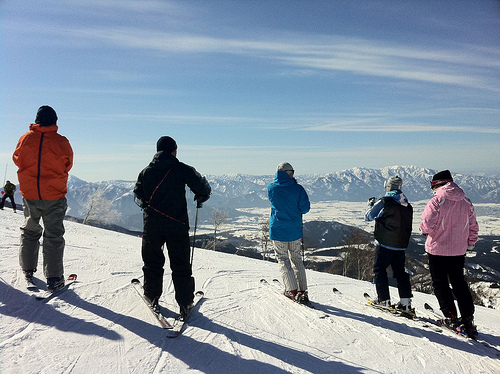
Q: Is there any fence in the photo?
A: No, there are no fences.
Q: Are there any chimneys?
A: No, there are no chimneys.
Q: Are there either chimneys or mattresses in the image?
A: No, there are no chimneys or mattresses.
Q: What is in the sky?
A: The clouds are in the sky.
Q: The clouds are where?
A: The clouds are in the sky.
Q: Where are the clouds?
A: The clouds are in the sky.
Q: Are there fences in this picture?
A: No, there are no fences.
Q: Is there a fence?
A: No, there are no fences.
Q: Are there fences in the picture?
A: No, there are no fences.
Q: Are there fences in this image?
A: No, there are no fences.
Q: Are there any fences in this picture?
A: No, there are no fences.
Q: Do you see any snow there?
A: Yes, there is snow.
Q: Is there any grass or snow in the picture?
A: Yes, there is snow.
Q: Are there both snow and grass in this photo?
A: No, there is snow but no grass.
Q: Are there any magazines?
A: No, there are no magazines.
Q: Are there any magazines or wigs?
A: No, there are no magazines or wigs.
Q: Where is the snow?
A: The snow is on the ground.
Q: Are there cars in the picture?
A: No, there are no cars.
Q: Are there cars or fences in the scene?
A: No, there are no cars or fences.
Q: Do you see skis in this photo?
A: Yes, there are skis.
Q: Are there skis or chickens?
A: Yes, there are skis.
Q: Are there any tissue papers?
A: No, there are no tissue papers.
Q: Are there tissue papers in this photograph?
A: No, there are no tissue papers.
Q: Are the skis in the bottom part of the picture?
A: Yes, the skis are in the bottom of the image.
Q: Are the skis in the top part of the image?
A: No, the skis are in the bottom of the image.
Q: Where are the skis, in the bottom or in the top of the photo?
A: The skis are in the bottom of the image.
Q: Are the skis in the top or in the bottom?
A: The skis are in the bottom of the image.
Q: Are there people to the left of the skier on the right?
A: Yes, there is a person to the left of the skier.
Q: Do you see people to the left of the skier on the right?
A: Yes, there is a person to the left of the skier.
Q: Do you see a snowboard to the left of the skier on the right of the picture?
A: No, there is a person to the left of the skier.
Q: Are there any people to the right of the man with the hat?
A: Yes, there is a person to the right of the man.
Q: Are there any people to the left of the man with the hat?
A: No, the person is to the right of the man.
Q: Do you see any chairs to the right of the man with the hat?
A: No, there is a person to the right of the man.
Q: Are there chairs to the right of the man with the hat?
A: No, there is a person to the right of the man.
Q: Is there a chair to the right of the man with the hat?
A: No, there is a person to the right of the man.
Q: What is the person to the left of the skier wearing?
A: The person is wearing a jacket.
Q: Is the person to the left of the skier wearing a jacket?
A: Yes, the person is wearing a jacket.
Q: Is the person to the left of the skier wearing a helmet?
A: No, the person is wearing a jacket.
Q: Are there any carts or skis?
A: Yes, there are skis.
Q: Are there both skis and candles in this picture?
A: No, there are skis but no candles.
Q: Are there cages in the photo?
A: No, there are no cages.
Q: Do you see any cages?
A: No, there are no cages.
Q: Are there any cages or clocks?
A: No, there are no cages or clocks.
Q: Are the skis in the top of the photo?
A: No, the skis are in the bottom of the image.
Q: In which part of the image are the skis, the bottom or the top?
A: The skis are in the bottom of the image.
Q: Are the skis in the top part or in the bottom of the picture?
A: The skis are in the bottom of the image.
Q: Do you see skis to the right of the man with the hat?
A: Yes, there are skis to the right of the man.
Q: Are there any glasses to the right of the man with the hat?
A: No, there are skis to the right of the man.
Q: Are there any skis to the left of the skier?
A: Yes, there are skis to the left of the skier.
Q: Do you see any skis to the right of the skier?
A: No, the skis are to the left of the skier.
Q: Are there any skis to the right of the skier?
A: No, the skis are to the left of the skier.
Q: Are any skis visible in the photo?
A: Yes, there are skis.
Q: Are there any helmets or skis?
A: Yes, there are skis.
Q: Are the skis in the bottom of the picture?
A: Yes, the skis are in the bottom of the image.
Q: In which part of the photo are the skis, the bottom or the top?
A: The skis are in the bottom of the image.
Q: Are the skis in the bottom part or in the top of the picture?
A: The skis are in the bottom of the image.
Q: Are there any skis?
A: Yes, there are skis.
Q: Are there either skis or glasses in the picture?
A: Yes, there are skis.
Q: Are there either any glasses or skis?
A: Yes, there are skis.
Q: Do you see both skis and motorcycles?
A: No, there are skis but no motorcycles.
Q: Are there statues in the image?
A: No, there are no statues.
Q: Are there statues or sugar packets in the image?
A: No, there are no statues or sugar packets.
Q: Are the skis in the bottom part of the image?
A: Yes, the skis are in the bottom of the image.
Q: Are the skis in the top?
A: No, the skis are in the bottom of the image.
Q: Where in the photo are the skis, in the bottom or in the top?
A: The skis are in the bottom of the image.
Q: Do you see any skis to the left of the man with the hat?
A: Yes, there are skis to the left of the man.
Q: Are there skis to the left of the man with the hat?
A: Yes, there are skis to the left of the man.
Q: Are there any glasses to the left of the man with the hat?
A: No, there are skis to the left of the man.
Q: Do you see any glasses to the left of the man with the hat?
A: No, there are skis to the left of the man.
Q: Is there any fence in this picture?
A: No, there are no fences.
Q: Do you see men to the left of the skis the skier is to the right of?
A: Yes, there is a man to the left of the skis.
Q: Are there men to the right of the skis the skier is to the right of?
A: No, the man is to the left of the skis.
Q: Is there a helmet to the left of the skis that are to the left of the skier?
A: No, there is a man to the left of the skis.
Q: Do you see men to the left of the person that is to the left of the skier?
A: Yes, there is a man to the left of the person.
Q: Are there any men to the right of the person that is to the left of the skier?
A: No, the man is to the left of the person.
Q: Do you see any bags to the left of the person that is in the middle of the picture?
A: No, there is a man to the left of the person.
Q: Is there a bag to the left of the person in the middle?
A: No, there is a man to the left of the person.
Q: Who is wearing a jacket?
A: The man is wearing a jacket.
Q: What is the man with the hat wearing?
A: The man is wearing a jacket.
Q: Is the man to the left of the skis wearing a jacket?
A: Yes, the man is wearing a jacket.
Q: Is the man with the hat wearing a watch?
A: No, the man is wearing a jacket.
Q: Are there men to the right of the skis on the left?
A: Yes, there is a man to the right of the skis.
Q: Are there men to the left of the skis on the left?
A: No, the man is to the right of the skis.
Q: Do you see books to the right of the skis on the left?
A: No, there is a man to the right of the skis.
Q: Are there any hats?
A: Yes, there is a hat.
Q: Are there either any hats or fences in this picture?
A: Yes, there is a hat.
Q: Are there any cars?
A: No, there are no cars.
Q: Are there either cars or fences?
A: No, there are no cars or fences.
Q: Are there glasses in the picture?
A: No, there are no glasses.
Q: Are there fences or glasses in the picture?
A: No, there are no glasses or fences.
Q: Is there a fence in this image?
A: No, there are no fences.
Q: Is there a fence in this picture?
A: No, there are no fences.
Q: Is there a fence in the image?
A: No, there are no fences.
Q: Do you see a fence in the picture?
A: No, there are no fences.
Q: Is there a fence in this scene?
A: No, there are no fences.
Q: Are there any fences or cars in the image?
A: No, there are no fences or cars.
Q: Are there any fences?
A: No, there are no fences.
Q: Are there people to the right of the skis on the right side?
A: Yes, there is a person to the right of the skis.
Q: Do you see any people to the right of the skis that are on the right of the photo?
A: Yes, there is a person to the right of the skis.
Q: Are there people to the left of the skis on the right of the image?
A: No, the person is to the right of the skis.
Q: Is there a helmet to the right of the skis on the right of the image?
A: No, there is a person to the right of the skis.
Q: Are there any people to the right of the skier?
A: Yes, there is a person to the right of the skier.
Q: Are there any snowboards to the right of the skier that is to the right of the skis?
A: No, there is a person to the right of the skier.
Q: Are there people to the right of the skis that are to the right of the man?
A: Yes, there is a person to the right of the skis.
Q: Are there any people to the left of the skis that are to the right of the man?
A: No, the person is to the right of the skis.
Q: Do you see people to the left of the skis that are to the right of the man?
A: No, the person is to the right of the skis.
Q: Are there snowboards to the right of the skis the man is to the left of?
A: No, there is a person to the right of the skis.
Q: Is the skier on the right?
A: Yes, the skier is on the right of the image.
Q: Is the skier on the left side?
A: No, the skier is on the right of the image.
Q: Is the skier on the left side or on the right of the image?
A: The skier is on the right of the image.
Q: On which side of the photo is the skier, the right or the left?
A: The skier is on the right of the image.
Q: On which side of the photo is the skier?
A: The skier is on the right of the image.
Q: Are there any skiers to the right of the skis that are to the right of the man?
A: Yes, there is a skier to the right of the skis.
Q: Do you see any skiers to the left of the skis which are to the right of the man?
A: No, the skier is to the right of the skis.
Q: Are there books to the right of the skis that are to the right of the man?
A: No, there is a skier to the right of the skis.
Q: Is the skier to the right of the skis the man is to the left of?
A: Yes, the skier is to the right of the skis.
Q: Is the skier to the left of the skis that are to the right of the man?
A: No, the skier is to the right of the skis.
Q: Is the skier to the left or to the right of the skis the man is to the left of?
A: The skier is to the right of the skis.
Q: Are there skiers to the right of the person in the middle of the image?
A: Yes, there is a skier to the right of the person.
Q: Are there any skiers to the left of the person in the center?
A: No, the skier is to the right of the person.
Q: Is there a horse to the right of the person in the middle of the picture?
A: No, there is a skier to the right of the person.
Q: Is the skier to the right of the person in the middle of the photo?
A: Yes, the skier is to the right of the person.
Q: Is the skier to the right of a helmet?
A: No, the skier is to the right of the person.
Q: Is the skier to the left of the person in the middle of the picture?
A: No, the skier is to the right of the person.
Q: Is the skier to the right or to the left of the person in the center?
A: The skier is to the right of the person.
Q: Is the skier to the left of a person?
A: Yes, the skier is to the left of a person.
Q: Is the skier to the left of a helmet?
A: No, the skier is to the left of a person.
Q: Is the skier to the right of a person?
A: No, the skier is to the left of a person.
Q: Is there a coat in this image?
A: Yes, there is a coat.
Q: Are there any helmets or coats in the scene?
A: Yes, there is a coat.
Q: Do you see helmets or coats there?
A: Yes, there is a coat.